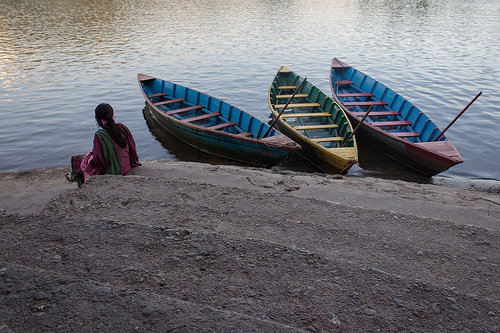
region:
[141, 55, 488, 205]
three small boats on the shore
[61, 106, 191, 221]
a woman sitting on the shore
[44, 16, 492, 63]
the calm serene water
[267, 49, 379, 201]
a boat with yellow slats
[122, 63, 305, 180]
a small blue and red rowing boat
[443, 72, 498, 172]
the oar or paddle for the boat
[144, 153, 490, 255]
the sand on the shore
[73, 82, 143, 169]
long brown hair in a pony tail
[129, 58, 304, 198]
The first boat on the left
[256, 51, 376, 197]
the second boat in the middle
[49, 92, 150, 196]
girl sitting in the sand next to the boats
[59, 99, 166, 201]
girl wearing a pink dress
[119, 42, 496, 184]
three boats in the water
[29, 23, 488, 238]
three boats and a girl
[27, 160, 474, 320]
the sand in front of the boats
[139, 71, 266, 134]
blue part of the first boat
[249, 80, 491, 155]
used to steer the boats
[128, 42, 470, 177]
three canoes in the water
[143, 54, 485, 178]
three canoes in the water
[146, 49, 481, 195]
three canoes in the water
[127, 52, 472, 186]
three canoes in the water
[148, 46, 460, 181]
three canoes in the water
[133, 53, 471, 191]
three canoes in the water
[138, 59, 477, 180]
three canoes in the water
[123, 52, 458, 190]
three canoes in the water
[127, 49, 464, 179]
three canoes in the water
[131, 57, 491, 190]
three canoes in the water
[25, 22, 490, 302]
Woman sits next to three row boats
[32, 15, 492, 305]
Woman with pink dress sits to multicolored boats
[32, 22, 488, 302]
Woman with dress and scarf sits on rock next to boats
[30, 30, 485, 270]
Woman with black hair sits on sand next to river and boats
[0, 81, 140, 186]
Woman with long black hair sits near water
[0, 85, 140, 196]
Woman with long black hair and pink dress sits near ocean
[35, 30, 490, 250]
Woman with long black hair sits next to boats parked next to rocks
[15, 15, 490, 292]
Woman sits with legs crossed near boats on the lake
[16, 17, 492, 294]
Woman looks out at lake while sitting next to three empty boats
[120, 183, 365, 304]
dirt with tire marks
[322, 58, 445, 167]
boat painted red and blue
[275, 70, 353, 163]
boat painted yellow and green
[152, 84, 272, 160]
boat painted blue and red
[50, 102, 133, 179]
woman sitting in dirt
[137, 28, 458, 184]
river with boats in it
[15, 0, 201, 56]
water reflecting the sun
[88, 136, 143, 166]
woman wearing pink shirt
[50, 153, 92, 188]
woman with legs crossed